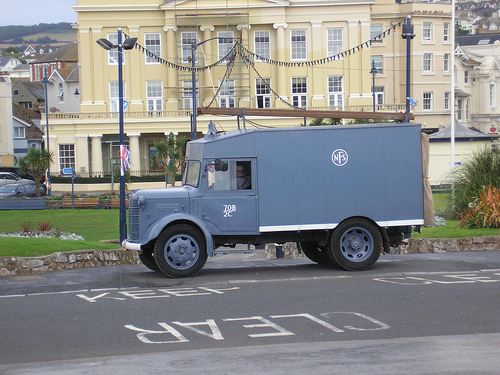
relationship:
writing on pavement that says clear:
[371, 268, 499, 287] [198, 328, 278, 338]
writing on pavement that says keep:
[58, 273, 265, 300] [108, 284, 134, 294]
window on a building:
[140, 76, 170, 116] [30, 100, 252, 244]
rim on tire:
[166, 235, 198, 270] [153, 218, 207, 275]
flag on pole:
[116, 143, 129, 172] [115, 25, 128, 245]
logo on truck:
[331, 148, 347, 165] [119, 123, 424, 271]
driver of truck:
[234, 164, 248, 187] [119, 123, 424, 271]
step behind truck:
[399, 234, 495, 254] [119, 123, 424, 271]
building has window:
[0, 0, 500, 194] [177, 31, 198, 63]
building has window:
[0, 0, 500, 194] [253, 31, 271, 63]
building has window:
[28, 5, 473, 166] [324, 25, 344, 54]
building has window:
[0, 0, 500, 194] [108, 78, 128, 114]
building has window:
[0, 0, 500, 194] [141, 78, 166, 116]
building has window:
[0, 0, 500, 194] [330, 73, 342, 107]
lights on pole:
[95, 33, 144, 54] [112, 22, 128, 249]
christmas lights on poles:
[124, 20, 405, 110] [104, 9, 422, 132]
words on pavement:
[73, 269, 394, 350] [0, 253, 500, 375]